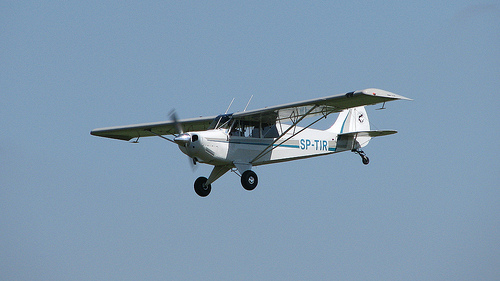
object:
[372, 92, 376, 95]
light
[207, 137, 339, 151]
stripe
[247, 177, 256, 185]
gear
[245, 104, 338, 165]
pole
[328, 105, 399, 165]
tail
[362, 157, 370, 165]
tail wheel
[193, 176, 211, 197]
front wheels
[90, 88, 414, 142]
wing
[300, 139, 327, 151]
sp-tir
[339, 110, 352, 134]
stripe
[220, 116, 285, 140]
cockpit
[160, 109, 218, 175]
propeller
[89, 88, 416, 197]
airplane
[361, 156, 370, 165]
wheel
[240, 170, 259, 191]
tire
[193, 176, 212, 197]
tire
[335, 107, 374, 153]
rudder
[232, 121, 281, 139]
windows